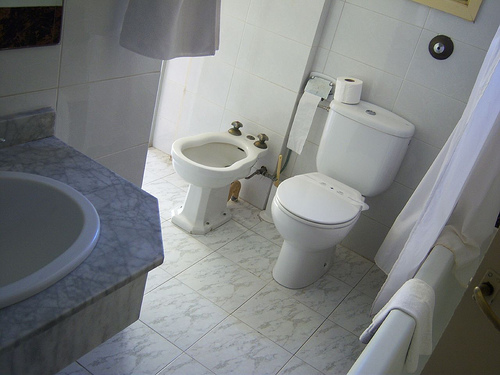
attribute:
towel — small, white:
[357, 271, 449, 371]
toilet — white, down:
[262, 88, 419, 294]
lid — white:
[271, 156, 370, 258]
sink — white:
[0, 167, 101, 307]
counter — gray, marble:
[0, 129, 163, 349]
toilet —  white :
[161, 135, 241, 171]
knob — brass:
[228, 117, 245, 139]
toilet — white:
[168, 118, 273, 240]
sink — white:
[4, 177, 146, 321]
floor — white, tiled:
[158, 250, 319, 362]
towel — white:
[361, 281, 455, 370]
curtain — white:
[396, 46, 497, 248]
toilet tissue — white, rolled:
[326, 55, 388, 122]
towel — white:
[130, 0, 244, 70]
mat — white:
[355, 278, 454, 368]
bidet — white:
[170, 125, 262, 236]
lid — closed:
[268, 156, 375, 269]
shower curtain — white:
[364, 29, 496, 318]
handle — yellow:
[270, 151, 285, 183]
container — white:
[253, 183, 278, 228]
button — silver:
[362, 104, 378, 119]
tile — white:
[231, 283, 326, 357]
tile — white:
[167, 249, 273, 318]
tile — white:
[76, 322, 185, 372]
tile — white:
[291, 314, 362, 373]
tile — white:
[210, 225, 279, 288]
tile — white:
[142, 179, 184, 227]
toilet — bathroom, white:
[265, 101, 415, 292]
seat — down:
[273, 192, 361, 229]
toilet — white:
[240, 158, 416, 354]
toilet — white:
[177, 116, 445, 360]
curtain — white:
[332, 93, 484, 313]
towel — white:
[347, 252, 464, 352]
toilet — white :
[241, 90, 427, 318]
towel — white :
[330, 246, 449, 353]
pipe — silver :
[274, 41, 329, 171]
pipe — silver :
[236, 27, 416, 260]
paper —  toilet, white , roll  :
[330, 75, 365, 105]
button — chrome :
[363, 105, 374, 115]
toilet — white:
[274, 98, 405, 289]